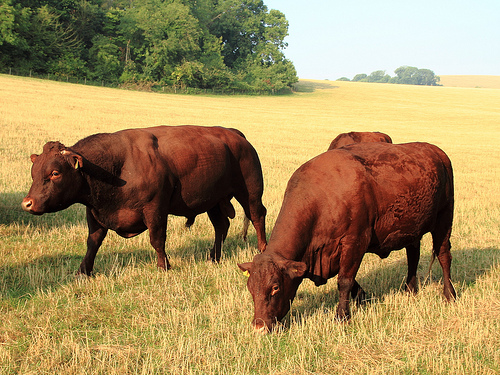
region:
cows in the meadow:
[9, 73, 489, 368]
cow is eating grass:
[231, 135, 465, 348]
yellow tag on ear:
[232, 255, 260, 282]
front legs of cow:
[332, 268, 374, 328]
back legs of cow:
[393, 231, 457, 306]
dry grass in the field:
[0, 90, 499, 373]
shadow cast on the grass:
[8, 235, 140, 320]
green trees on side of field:
[1, 3, 373, 124]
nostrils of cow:
[16, 193, 35, 216]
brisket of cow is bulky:
[93, 197, 153, 244]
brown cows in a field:
[16, 107, 471, 332]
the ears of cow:
[228, 255, 310, 282]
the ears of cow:
[22, 148, 86, 171]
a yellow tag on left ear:
[228, 258, 255, 285]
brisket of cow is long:
[307, 251, 337, 288]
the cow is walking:
[16, 115, 276, 279]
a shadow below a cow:
[331, 230, 493, 327]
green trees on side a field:
[0, 0, 330, 120]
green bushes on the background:
[322, 60, 460, 96]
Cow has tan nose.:
[17, 188, 41, 209]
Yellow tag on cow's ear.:
[69, 155, 101, 177]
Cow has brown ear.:
[66, 153, 121, 188]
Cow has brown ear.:
[20, 146, 46, 171]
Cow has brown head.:
[30, 134, 89, 181]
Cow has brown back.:
[135, 123, 264, 155]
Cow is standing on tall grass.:
[61, 189, 260, 309]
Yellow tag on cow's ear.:
[237, 253, 264, 293]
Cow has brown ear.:
[282, 250, 312, 275]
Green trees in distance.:
[221, 60, 294, 82]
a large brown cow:
[19, 125, 266, 277]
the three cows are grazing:
[21, 123, 454, 332]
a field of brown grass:
[2, 74, 498, 371]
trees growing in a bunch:
[0, 0, 298, 95]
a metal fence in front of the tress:
[1, 64, 291, 98]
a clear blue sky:
[218, 0, 497, 79]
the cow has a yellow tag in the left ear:
[18, 122, 266, 275]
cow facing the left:
[22, 125, 266, 277]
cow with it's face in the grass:
[0, 190, 497, 312]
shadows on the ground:
[1, 186, 497, 331]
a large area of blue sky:
[221, 0, 498, 81]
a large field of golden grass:
[0, 72, 499, 374]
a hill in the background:
[433, 74, 498, 89]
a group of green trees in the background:
[323, 64, 443, 86]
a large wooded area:
[0, 0, 298, 96]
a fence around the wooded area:
[0, 65, 295, 95]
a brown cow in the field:
[20, 124, 268, 279]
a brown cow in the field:
[236, 141, 456, 333]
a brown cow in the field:
[326, 130, 392, 151]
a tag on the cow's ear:
[240, 269, 250, 276]